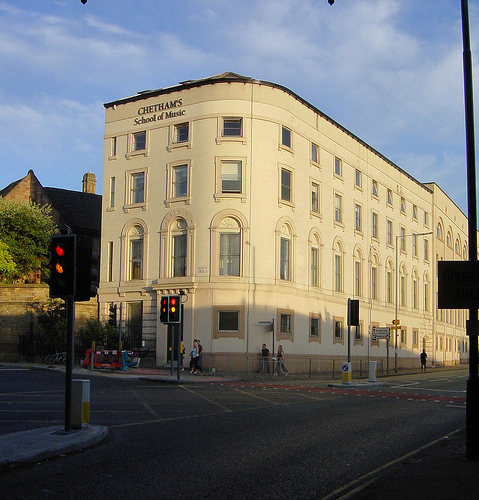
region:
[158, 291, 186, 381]
A stoplight on a street corner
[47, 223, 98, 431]
Stop light on a median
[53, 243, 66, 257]
Red light on a stop light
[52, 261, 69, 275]
Orange light on a stop light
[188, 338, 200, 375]
Woman wearing a light blue shirt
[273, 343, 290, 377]
Woman wearing gray on the street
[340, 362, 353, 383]
An electronic box on a median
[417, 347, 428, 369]
A man walking down the street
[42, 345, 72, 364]
A bicycle parked on a side walk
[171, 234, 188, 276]
A window on a building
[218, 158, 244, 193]
A window on a building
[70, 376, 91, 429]
A metal box on a median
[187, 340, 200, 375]
A lady walking on a side walk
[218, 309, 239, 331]
Small window on a building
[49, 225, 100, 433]
A stop light on a street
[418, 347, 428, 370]
A guy walking on the side walk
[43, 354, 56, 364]
Back tire on a bike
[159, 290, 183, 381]
Stop light on yellow and red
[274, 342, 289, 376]
Girl wearing gray pants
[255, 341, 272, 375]
Guy wearing a black tee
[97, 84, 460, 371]
a large white building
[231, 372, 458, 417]
a crosswalk painted red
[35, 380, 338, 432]
a few yellow lines in the street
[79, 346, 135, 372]
a red and white barrier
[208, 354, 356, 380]
a simple metal fence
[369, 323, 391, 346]
a pair of street signs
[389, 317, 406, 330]
a bright yellow sign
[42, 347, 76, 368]
a bike leaning on a fence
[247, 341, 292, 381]
a couple walking outside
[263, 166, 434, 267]
a row of windows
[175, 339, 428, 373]
the people in front of the building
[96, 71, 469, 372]
the large building on the corner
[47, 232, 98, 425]
the traffic light on the island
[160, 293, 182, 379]
the traffic lights on the sidewalk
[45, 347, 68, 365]
the bike near the building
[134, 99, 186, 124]
the words on the building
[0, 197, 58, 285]
the tree near the building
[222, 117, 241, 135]
the window on the building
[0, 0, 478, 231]
the clouds in the blue sky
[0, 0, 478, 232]
the blue sky with clouds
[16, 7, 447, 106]
the sky is blue and clear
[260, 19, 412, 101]
the clouds in the sky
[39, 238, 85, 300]
the traffic light is red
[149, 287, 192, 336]
the traffic light is red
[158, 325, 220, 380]
people beside the building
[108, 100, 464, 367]
the building is tan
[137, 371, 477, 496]
the street is empty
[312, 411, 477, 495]
the yellow line on the road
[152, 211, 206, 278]
the window on the building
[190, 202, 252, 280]
the window on the building